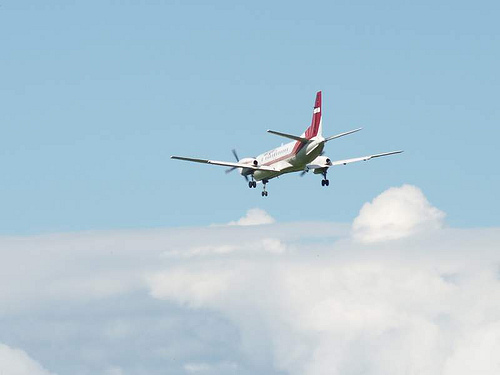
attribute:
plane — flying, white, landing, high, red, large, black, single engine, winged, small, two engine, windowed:
[170, 98, 428, 207]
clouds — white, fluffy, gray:
[67, 271, 487, 369]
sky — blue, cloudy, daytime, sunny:
[22, 11, 455, 163]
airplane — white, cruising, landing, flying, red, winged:
[147, 77, 423, 216]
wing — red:
[158, 126, 429, 167]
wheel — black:
[240, 175, 266, 197]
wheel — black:
[311, 172, 332, 200]